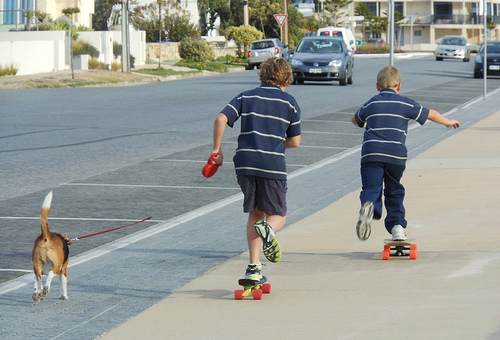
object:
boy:
[351, 65, 460, 241]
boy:
[211, 57, 301, 282]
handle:
[205, 154, 224, 165]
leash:
[68, 215, 159, 243]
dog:
[31, 189, 70, 298]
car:
[287, 35, 356, 85]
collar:
[57, 234, 70, 245]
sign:
[273, 14, 289, 25]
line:
[61, 182, 241, 189]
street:
[0, 47, 500, 339]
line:
[3, 215, 162, 224]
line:
[300, 143, 345, 151]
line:
[299, 128, 363, 135]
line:
[306, 118, 353, 125]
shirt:
[355, 90, 428, 163]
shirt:
[220, 84, 301, 181]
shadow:
[277, 249, 382, 262]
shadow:
[67, 286, 235, 298]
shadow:
[6, 275, 33, 302]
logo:
[311, 62, 319, 66]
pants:
[361, 160, 411, 232]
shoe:
[390, 225, 407, 240]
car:
[434, 34, 471, 62]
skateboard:
[382, 238, 417, 260]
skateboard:
[235, 278, 271, 299]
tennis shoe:
[254, 220, 281, 264]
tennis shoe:
[245, 263, 263, 280]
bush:
[179, 37, 219, 70]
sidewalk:
[131, 60, 196, 73]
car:
[247, 38, 289, 69]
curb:
[0, 66, 257, 91]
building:
[395, 0, 500, 51]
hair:
[259, 57, 294, 87]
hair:
[375, 67, 401, 91]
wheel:
[252, 289, 262, 300]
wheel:
[262, 284, 271, 293]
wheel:
[233, 289, 244, 299]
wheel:
[409, 249, 416, 259]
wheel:
[381, 251, 391, 261]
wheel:
[409, 243, 417, 249]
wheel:
[383, 245, 391, 250]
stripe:
[238, 129, 285, 142]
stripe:
[361, 139, 406, 147]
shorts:
[235, 172, 288, 217]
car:
[474, 41, 500, 79]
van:
[285, 28, 362, 84]